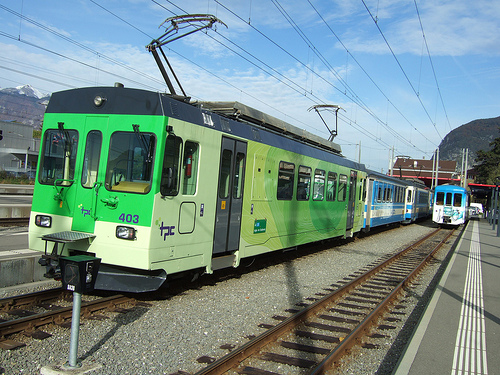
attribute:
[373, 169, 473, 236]
train — blue , white 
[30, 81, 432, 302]
train cars — black 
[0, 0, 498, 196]
blue sky — blue 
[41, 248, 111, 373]
signal box — black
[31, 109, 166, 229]
front — green 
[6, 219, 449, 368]
gray gravel — gray 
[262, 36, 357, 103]
white clouds — white 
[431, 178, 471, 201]
blue top — blue 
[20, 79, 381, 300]
train — blue , black 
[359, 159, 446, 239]
train car — blue  , white   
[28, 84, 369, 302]
green train — green 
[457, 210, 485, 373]
white lines — white 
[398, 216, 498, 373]
pedestrian walkway — grey , white 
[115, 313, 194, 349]
grey gravels — grey 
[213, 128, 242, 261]
doors — dark grey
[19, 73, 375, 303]
trolley — green